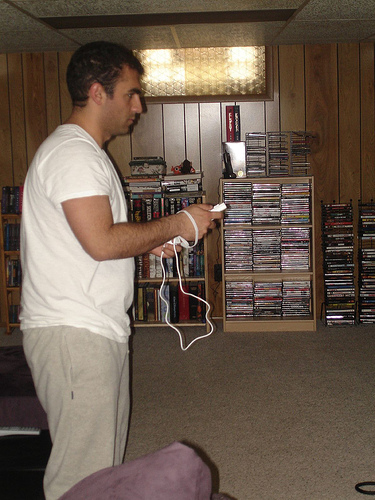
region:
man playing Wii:
[15, 36, 244, 495]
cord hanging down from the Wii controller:
[150, 241, 226, 358]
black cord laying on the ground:
[350, 475, 374, 498]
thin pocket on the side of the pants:
[57, 336, 78, 396]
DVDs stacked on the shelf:
[215, 176, 321, 330]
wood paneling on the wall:
[1, 44, 373, 322]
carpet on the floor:
[0, 319, 374, 498]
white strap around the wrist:
[171, 205, 206, 250]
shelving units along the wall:
[1, 135, 373, 329]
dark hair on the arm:
[105, 212, 186, 264]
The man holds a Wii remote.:
[161, 201, 230, 238]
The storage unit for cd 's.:
[214, 175, 317, 331]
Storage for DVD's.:
[321, 200, 371, 328]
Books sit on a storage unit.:
[125, 155, 203, 191]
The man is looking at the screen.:
[62, 39, 149, 133]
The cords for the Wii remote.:
[157, 245, 220, 349]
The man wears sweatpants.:
[17, 322, 152, 477]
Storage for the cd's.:
[243, 130, 311, 173]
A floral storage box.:
[127, 155, 172, 172]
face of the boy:
[72, 42, 176, 154]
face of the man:
[61, 51, 175, 149]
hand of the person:
[80, 210, 167, 255]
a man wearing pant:
[29, 311, 185, 478]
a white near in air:
[171, 234, 233, 359]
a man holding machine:
[160, 181, 250, 249]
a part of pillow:
[128, 439, 203, 496]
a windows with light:
[148, 32, 330, 124]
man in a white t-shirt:
[16, 53, 230, 499]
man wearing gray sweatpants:
[12, 45, 226, 498]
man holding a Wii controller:
[15, 38, 233, 486]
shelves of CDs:
[218, 175, 317, 333]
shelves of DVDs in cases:
[320, 195, 374, 335]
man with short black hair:
[13, 42, 218, 489]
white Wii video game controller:
[146, 197, 230, 352]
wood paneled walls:
[0, 39, 374, 201]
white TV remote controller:
[0, 420, 45, 440]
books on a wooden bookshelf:
[127, 156, 211, 332]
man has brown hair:
[68, 27, 117, 119]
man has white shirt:
[3, 108, 133, 324]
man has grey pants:
[28, 332, 120, 499]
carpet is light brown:
[224, 357, 309, 433]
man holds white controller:
[138, 187, 219, 363]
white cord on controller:
[136, 235, 206, 342]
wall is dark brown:
[297, 52, 373, 136]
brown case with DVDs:
[211, 157, 319, 335]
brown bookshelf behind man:
[129, 179, 210, 310]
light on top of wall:
[117, 45, 297, 102]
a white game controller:
[208, 197, 225, 216]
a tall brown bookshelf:
[221, 175, 320, 331]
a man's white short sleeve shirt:
[17, 123, 143, 344]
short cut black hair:
[64, 40, 145, 117]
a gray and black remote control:
[0, 422, 43, 443]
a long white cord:
[159, 242, 212, 350]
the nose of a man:
[129, 92, 144, 113]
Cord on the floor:
[352, 475, 374, 495]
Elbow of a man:
[84, 239, 111, 268]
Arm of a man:
[110, 215, 176, 257]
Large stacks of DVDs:
[226, 231, 251, 271]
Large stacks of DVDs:
[252, 228, 281, 271]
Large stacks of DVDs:
[278, 227, 308, 272]